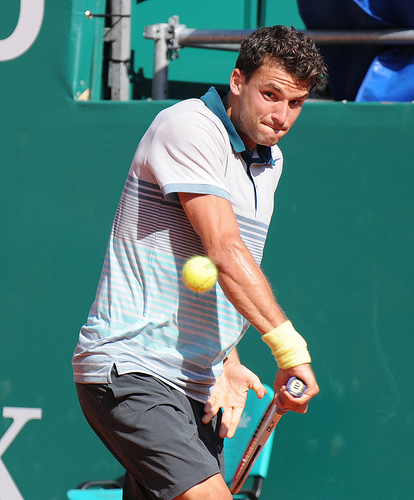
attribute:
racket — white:
[223, 368, 313, 497]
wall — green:
[5, 117, 101, 231]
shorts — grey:
[68, 348, 243, 498]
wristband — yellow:
[261, 320, 305, 369]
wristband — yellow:
[259, 320, 311, 369]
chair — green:
[65, 382, 275, 499]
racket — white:
[229, 375, 306, 495]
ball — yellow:
[174, 251, 246, 311]